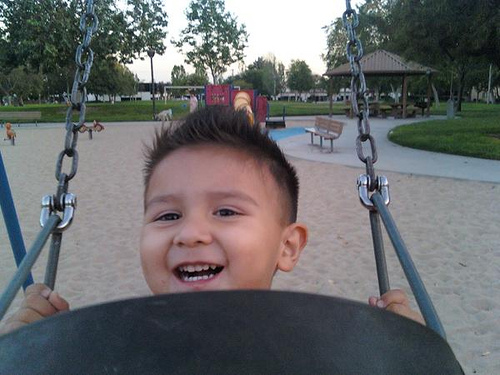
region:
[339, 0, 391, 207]
Metal chain on a swing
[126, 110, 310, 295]
Boy smiling on a swing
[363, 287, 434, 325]
Boy holding on to a swing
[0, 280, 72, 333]
Boy's right hand on a swing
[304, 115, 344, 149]
Bench at a playground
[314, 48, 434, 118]
Shelter behind a playground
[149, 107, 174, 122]
Dog walking in the park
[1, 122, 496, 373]
Sand on a playground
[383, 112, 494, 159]
Grassy area in a park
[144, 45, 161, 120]
Light pole over a playground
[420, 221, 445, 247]
Small patch of brown sand in the park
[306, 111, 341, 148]
Brown wooden bench on sidewalk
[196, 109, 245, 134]
Black hair of the little boy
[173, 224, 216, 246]
Nose of the little boy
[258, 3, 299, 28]
Small patch of the white sky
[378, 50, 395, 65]
Small part of the brown roof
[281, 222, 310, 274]
Left ear of the little boy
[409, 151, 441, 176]
Medium section of the gray sidewalk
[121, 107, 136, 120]
Small patch of the green grass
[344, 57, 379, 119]
Metal chain on the swing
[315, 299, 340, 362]
There is a black tire that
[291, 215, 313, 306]
This boy has an ear that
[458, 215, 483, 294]
There is a pebbled surface here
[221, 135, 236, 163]
This boy has brown hair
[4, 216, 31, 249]
There is a blue stand here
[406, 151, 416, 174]
There is a slab of cement visible here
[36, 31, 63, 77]
There are dark trees in the distance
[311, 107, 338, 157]
There is a wooden bench visible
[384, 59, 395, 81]
There is a shelter that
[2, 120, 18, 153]
There is a rocking horse here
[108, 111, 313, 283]
a boy is posed for a picture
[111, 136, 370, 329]
the boy is on aswiging board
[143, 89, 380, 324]
th boy is laughng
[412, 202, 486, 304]
floor is coverd of sand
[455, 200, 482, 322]
floor is brown uin color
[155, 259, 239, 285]
teeth are white in color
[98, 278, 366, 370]
the board is black in color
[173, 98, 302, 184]
hair is black in color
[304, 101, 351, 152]
a bench is next to the beach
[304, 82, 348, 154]
the bench is wooden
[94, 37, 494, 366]
A BOY IN THE PARK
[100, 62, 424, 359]
a young boy in the park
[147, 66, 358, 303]
a boy with dark hair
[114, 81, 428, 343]
a young boy with dark hair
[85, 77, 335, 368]
a boy that is smiling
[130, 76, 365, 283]
a young boy that is smiling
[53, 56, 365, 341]
a boy on a swing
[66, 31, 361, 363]
a young boy on a swing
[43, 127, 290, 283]
a ground covered in sand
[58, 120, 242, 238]
sand covering the ground